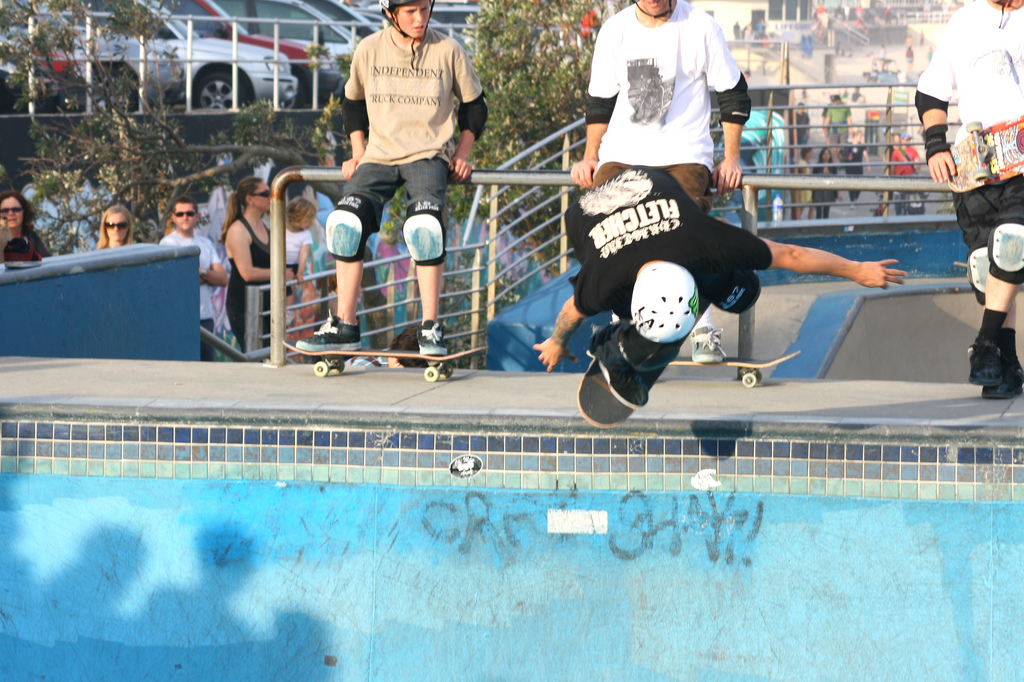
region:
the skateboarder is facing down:
[532, 163, 900, 427]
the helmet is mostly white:
[629, 260, 700, 343]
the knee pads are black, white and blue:
[324, 193, 448, 269]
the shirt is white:
[585, 0, 744, 178]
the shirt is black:
[557, 165, 772, 320]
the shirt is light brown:
[342, 26, 483, 172]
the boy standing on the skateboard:
[282, 0, 488, 384]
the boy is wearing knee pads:
[279, 0, 491, 378]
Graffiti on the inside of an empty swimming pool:
[426, 479, 772, 579]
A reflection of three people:
[22, 498, 346, 676]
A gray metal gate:
[227, 245, 519, 367]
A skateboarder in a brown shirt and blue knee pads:
[283, 4, 515, 387]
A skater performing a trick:
[526, 156, 907, 428]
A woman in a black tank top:
[215, 174, 295, 353]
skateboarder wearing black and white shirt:
[514, 155, 889, 418]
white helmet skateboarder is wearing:
[614, 264, 698, 344]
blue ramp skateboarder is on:
[6, 412, 1022, 681]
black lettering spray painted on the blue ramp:
[405, 469, 776, 564]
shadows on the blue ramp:
[10, 490, 327, 681]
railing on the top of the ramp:
[262, 155, 1009, 365]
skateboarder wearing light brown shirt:
[325, 6, 482, 329]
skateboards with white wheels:
[256, 320, 789, 396]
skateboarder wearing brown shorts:
[575, 6, 772, 351]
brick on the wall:
[816, 465, 839, 484]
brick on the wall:
[956, 446, 976, 470]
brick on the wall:
[105, 414, 162, 443]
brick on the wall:
[258, 448, 282, 467]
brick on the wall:
[375, 429, 421, 461]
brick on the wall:
[570, 451, 602, 472]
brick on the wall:
[813, 442, 851, 461]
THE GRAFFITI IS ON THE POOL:
[383, 459, 792, 576]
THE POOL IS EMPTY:
[0, 389, 1019, 674]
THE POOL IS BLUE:
[2, 397, 1021, 679]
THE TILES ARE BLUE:
[0, 394, 1019, 492]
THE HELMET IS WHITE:
[623, 258, 697, 363]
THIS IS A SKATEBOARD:
[555, 295, 707, 439]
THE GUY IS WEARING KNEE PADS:
[304, 194, 470, 272]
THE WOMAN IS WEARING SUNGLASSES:
[90, 204, 144, 255]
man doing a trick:
[458, 111, 912, 469]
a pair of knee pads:
[317, 170, 451, 282]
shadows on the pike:
[18, 446, 351, 678]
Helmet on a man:
[620, 253, 709, 349]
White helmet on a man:
[623, 265, 710, 351]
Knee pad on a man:
[395, 193, 452, 273]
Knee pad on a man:
[318, 192, 380, 273]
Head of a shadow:
[189, 511, 263, 595]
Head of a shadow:
[79, 515, 159, 588]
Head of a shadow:
[268, 604, 342, 666]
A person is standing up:
[9, 200, 58, 265]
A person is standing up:
[809, 140, 841, 211]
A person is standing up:
[790, 100, 811, 143]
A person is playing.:
[322, 4, 490, 362]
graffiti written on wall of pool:
[412, 486, 764, 575]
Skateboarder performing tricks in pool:
[529, 168, 916, 429]